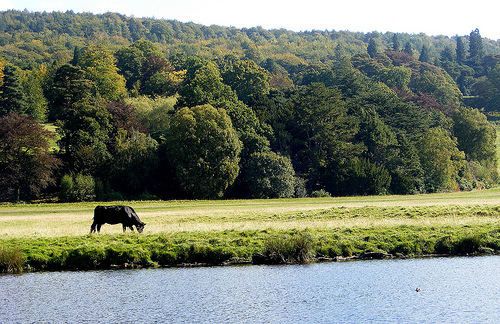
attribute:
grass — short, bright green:
[0, 185, 500, 270]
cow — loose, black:
[82, 197, 150, 237]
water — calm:
[1, 250, 498, 320]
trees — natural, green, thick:
[20, 7, 488, 198]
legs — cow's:
[127, 224, 134, 233]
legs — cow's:
[120, 222, 125, 232]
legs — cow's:
[97, 221, 101, 233]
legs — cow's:
[91, 223, 93, 233]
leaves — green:
[93, 61, 290, 153]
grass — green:
[1, 183, 498, 278]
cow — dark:
[87, 203, 146, 235]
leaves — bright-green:
[434, 140, 456, 160]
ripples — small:
[144, 298, 195, 305]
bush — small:
[264, 240, 316, 263]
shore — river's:
[1, 234, 499, 261]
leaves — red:
[114, 106, 131, 122]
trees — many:
[2, 37, 156, 197]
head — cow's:
[133, 220, 147, 232]